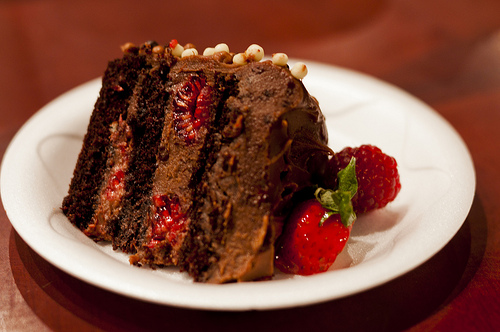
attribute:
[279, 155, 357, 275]
strawberry — sliced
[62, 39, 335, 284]
cake — sliced,  chocolate, cut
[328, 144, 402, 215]
raspberry — red, round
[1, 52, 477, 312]
bowl — round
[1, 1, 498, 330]
table — wooden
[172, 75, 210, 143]
sauce — red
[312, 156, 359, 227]
leaf — green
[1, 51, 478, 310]
dish — white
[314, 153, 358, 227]
leaves — green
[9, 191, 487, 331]
shadow —  dish's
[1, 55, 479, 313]
plate — white